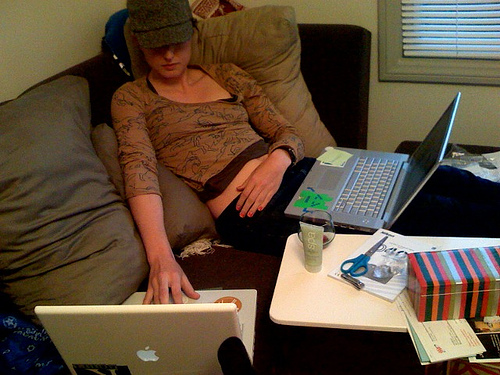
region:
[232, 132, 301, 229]
left hand on stomach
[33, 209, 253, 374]
right hand on computer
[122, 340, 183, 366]
logo of apple on computer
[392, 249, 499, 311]
striped box on table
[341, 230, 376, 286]
scissors on the table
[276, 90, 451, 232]
silver lapton on black table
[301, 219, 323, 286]
bottle of creme next to glass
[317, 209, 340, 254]
glasses with liquid in it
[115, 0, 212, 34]
hat on girl's head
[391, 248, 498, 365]
papers under the box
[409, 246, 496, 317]
a box of different colors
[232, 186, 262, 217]
her nails are red painted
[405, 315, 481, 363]
some documents under the box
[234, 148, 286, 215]
one hand of the girl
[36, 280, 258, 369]
this is an apple laptop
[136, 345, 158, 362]
the logo of Apple in white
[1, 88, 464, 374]
there are two laptops on the scene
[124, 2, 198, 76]
the head of the girl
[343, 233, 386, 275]
a blue scissors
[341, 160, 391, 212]
the keyboard of the laptop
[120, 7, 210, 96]
girl is wearing a cap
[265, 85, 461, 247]
a laptop on gir's lap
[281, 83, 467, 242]
open silver laptop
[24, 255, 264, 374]
open white laptop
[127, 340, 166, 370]
apple mac logo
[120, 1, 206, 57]
grey hat on woman's head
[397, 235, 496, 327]
striped box on table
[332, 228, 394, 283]
pair of blue handled scissors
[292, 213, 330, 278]
tube of lotion on table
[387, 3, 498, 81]
blinds covering window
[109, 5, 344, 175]
large throw pillow on sofa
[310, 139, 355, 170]
yellow stickie note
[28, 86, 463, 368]
two laptop computers in a casual setting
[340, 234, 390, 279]
pair of blue handled scirrors on a table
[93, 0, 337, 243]
large fluffy pillow being laid back on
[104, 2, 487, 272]
black pants and a brown shirt under a patterned shirt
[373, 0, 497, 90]
window with wood frame and Venetian blind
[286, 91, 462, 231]
silver lap top on a lap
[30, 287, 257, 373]
tan apple brand laptop computer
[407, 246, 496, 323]
red, blue, orange, red striped box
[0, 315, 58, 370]
blue patterned piece of cloth on a sofa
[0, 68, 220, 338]
fluffy pillow on a sofa